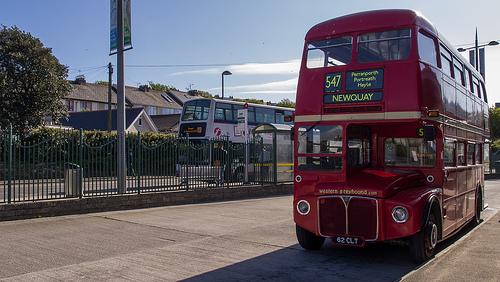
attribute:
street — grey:
[4, 177, 498, 278]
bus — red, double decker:
[288, 4, 493, 254]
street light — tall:
[218, 67, 235, 95]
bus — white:
[172, 87, 302, 186]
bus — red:
[301, 19, 492, 251]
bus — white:
[174, 89, 291, 186]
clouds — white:
[199, 51, 300, 100]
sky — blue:
[148, 7, 258, 52]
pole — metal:
[104, 13, 146, 195]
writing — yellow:
[323, 68, 379, 100]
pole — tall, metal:
[104, 12, 157, 199]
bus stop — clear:
[247, 115, 309, 183]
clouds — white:
[209, 52, 296, 99]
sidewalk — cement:
[402, 211, 499, 279]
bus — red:
[248, 11, 499, 278]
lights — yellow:
[350, 66, 385, 91]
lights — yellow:
[325, 68, 339, 85]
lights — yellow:
[325, 87, 385, 104]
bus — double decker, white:
[298, 39, 496, 236]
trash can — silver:
[64, 162, 84, 197]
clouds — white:
[171, 56, 298, 103]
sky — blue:
[4, 0, 296, 101]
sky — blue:
[134, 4, 300, 102]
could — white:
[174, 58, 297, 103]